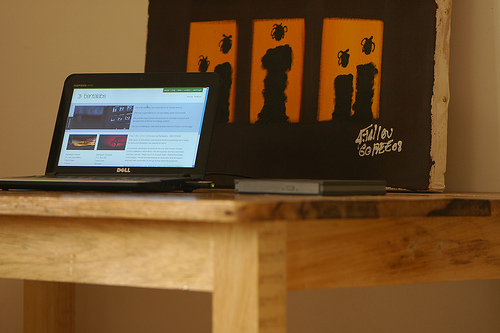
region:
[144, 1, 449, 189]
signed painting on rectangle canvas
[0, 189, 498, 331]
corner of plain wood table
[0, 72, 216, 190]
open laptop with glowing screen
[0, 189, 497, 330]
leg on corner of wood table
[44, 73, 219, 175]
company name below glowing screen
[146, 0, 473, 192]
shadow on wall behind painted canvas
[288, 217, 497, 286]
grain on wood surface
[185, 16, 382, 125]
three yellow painted panels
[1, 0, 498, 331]
plain tan wall behind table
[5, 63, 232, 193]
open black laptop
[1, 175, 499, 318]
light wooden table containing computer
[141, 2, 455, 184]
orange and black art work leaning against wall on desk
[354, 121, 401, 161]
white writing in corner of black painting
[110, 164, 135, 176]
silver brand of laptop visible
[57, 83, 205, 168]
lit computer screen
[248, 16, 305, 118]
orange painting of African American woman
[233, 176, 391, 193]
book laying on wooden table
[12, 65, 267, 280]
a laptop on a table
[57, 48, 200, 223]
a dell laptop on table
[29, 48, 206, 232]
a black dell laptop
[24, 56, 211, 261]
a black laptop on table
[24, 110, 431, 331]
a brown wooden table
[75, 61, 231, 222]
a laptop that is oepn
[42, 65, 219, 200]
a laptop that is open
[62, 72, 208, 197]
a laptop that is black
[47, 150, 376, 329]
a large brown table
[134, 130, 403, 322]
a large wooden table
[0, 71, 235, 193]
the opened up laptop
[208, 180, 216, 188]
the lit up green light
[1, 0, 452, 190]
the painting behind the laptop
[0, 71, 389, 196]
the external attached to the laptop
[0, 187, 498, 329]
the light colored wooden table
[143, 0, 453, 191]
the orange and black canvas painting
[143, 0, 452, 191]
the painting is signed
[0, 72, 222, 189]
the screen on the laptop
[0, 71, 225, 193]
the brand name on the laptop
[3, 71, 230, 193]
the word DELL on the laptop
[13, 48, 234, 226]
this is a laptop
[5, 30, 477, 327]
laptop on a table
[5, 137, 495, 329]
the table is wooden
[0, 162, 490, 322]
the table is brown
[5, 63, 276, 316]
a laptop on a table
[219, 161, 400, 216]
a book on a table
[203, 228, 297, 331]
the leg of a table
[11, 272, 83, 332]
the leg of a table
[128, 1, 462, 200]
a paint behind a laptop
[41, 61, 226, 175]
the screen of a laptop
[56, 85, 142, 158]
pictures on the screen